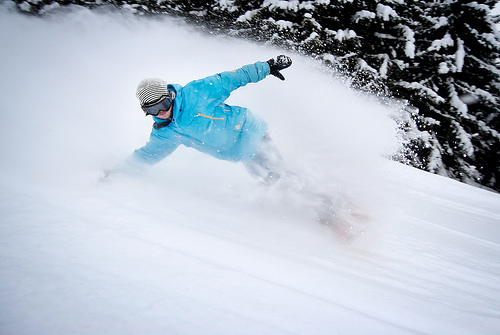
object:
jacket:
[120, 90, 300, 178]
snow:
[130, 217, 199, 277]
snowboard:
[320, 155, 379, 263]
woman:
[86, 42, 323, 201]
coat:
[131, 60, 269, 162]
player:
[93, 57, 333, 211]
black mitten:
[266, 51, 293, 80]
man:
[104, 49, 374, 241]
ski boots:
[305, 185, 366, 235]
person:
[109, 57, 388, 255]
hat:
[134, 75, 171, 103]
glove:
[267, 55, 312, 75]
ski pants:
[230, 124, 364, 250]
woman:
[32, 0, 397, 267]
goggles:
[140, 86, 179, 121]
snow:
[1, 126, 497, 333]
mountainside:
[1, 42, 489, 332]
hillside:
[9, 60, 494, 334]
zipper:
[196, 112, 224, 121]